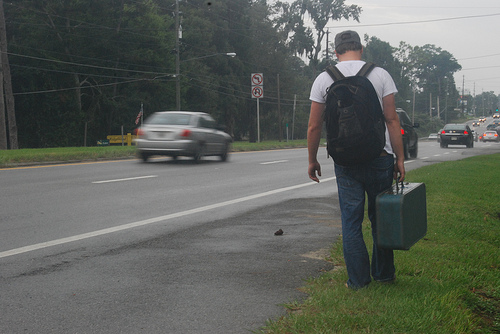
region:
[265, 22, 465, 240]
man walking down street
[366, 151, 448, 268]
man holding a briefcase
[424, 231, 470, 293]
green grass next to man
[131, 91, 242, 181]
car driving down street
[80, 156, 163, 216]
white line on road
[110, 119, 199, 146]
red lightson back of car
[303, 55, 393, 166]
backpack on man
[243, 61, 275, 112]
signs on top of each other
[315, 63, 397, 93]
white shirt on man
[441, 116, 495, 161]
many cars on the street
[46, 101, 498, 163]
traffic on a road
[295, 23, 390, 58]
man wearing a baseball cap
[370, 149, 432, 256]
man carrying a suitcase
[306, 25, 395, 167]
black backpack on man's back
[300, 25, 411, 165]
man wearing a white shirt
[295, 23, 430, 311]
man standing in the grass by the road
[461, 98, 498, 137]
approaching vehicles have their headlights on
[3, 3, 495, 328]
day appears grey and overcast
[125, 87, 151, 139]
a flag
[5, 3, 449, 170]
dark trees near grass on far side of the road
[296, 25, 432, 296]
man standing in grass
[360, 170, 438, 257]
suitcase in man's hand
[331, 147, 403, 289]
blue jeans on man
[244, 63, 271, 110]
two signs on pole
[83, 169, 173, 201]
white line in road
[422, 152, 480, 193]
grass on side of road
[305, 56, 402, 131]
white short sleeved tee shirt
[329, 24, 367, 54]
cap on man's head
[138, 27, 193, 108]
telephone pole and wires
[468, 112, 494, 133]
cars with headlights on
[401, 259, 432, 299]
part of a grass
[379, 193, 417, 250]
edge of a suit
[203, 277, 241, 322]
part of a road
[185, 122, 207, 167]
part of a wheel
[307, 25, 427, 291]
man wearing a black backpack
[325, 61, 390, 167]
brown and black backpack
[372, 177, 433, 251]
green suitcase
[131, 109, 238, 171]
gray vehicle on a street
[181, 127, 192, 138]
red car light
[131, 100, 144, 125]
USA flag on a pole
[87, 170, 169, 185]
white line on a street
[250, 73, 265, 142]
two no signs on a silver pole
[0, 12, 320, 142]
lots of green trees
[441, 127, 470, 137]
two lit red car lights